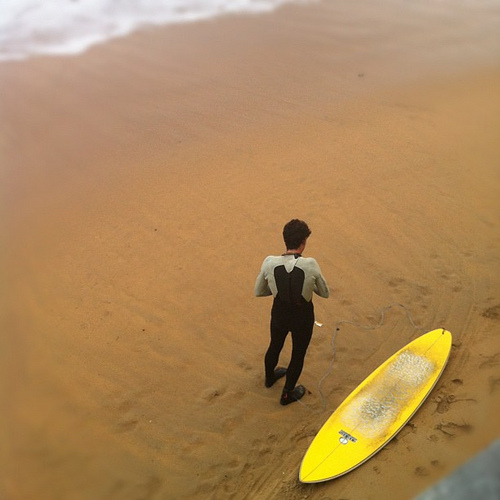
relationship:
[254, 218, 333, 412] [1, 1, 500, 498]
person on sand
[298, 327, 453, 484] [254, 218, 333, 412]
surfboard next to a person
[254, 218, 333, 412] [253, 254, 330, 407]
person wearing a wetsuit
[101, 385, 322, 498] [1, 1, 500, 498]
footprints on sand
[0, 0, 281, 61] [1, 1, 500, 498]
water on sand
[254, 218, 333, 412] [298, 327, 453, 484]
person next to surfboard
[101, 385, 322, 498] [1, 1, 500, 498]
footprints in sand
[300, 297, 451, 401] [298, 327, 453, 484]
cord attached to surfboard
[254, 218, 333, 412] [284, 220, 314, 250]
person has hair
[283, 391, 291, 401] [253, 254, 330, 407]
spot on wetsuit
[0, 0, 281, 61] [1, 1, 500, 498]
water coming up on sand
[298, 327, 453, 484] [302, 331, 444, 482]
surfboard has a stripe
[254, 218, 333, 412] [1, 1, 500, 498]
person in sand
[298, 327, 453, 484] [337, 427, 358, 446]
surfboard has a logo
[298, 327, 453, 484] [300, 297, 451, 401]
surfboard has a cord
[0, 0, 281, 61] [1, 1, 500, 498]
water by sand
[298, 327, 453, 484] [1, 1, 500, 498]
surfboard on sand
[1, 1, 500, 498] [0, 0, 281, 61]
sand near water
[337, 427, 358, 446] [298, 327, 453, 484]
logo on a surfboard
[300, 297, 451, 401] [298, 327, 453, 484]
cord to surfboard